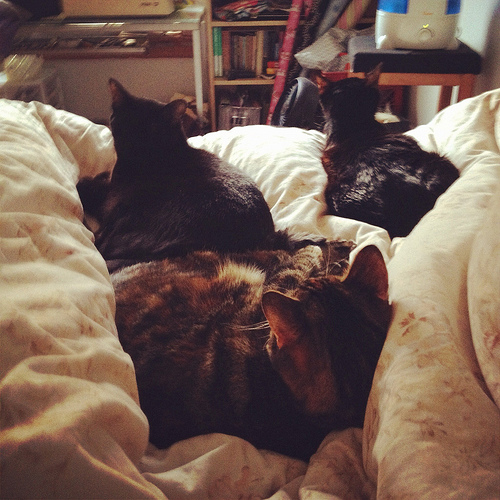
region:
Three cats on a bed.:
[31, 52, 479, 464]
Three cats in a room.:
[28, 54, 468, 451]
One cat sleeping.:
[66, 229, 465, 467]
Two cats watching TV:
[43, 52, 475, 257]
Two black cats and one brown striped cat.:
[49, 61, 464, 476]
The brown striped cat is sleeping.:
[62, 225, 450, 455]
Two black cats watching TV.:
[42, 52, 485, 257]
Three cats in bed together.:
[33, 58, 459, 498]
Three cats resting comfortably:
[41, 49, 482, 452]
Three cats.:
[56, 73, 466, 458]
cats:
[77, 57, 462, 467]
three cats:
[48, 60, 498, 463]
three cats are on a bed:
[69, 60, 492, 461]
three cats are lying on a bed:
[68, 65, 488, 457]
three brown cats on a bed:
[71, 57, 457, 465]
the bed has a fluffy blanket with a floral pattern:
[3, 93, 494, 498]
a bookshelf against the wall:
[203, 0, 360, 138]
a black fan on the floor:
[264, 74, 321, 139]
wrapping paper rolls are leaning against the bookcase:
[262, 1, 371, 131]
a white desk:
[20, 14, 217, 129]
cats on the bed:
[47, 42, 445, 490]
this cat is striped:
[95, 237, 417, 446]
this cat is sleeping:
[88, 225, 448, 477]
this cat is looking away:
[60, 73, 284, 263]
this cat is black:
[290, 64, 472, 243]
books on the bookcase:
[205, 15, 294, 85]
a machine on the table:
[369, 1, 469, 56]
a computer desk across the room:
[0, 0, 225, 115]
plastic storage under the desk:
[0, 48, 79, 110]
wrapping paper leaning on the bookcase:
[267, 4, 357, 139]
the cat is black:
[214, 127, 481, 249]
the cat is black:
[294, 39, 399, 196]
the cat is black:
[293, 35, 460, 272]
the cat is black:
[306, 115, 378, 242]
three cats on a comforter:
[89, 60, 453, 452]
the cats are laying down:
[91, 55, 438, 422]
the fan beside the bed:
[264, 71, 324, 136]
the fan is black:
[266, 70, 328, 127]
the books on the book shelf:
[206, 3, 307, 120]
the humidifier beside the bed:
[366, 0, 466, 55]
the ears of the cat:
[248, 237, 413, 341]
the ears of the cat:
[302, 57, 397, 91]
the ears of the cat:
[103, 62, 199, 126]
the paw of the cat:
[288, 237, 335, 269]